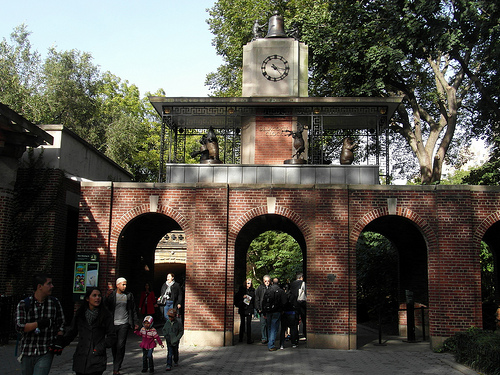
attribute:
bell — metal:
[254, 3, 295, 43]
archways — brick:
[123, 202, 437, 348]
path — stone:
[177, 341, 452, 374]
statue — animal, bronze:
[281, 124, 313, 169]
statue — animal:
[337, 117, 351, 167]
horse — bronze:
[273, 116, 317, 174]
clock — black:
[263, 52, 285, 85]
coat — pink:
[134, 318, 168, 349]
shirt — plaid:
[19, 287, 69, 353]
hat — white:
[112, 273, 132, 285]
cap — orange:
[163, 307, 176, 318]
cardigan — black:
[161, 277, 186, 308]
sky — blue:
[9, 6, 224, 92]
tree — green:
[236, 2, 458, 185]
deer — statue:
[192, 120, 223, 177]